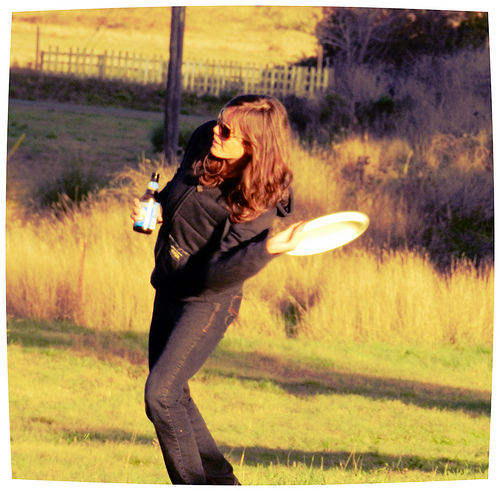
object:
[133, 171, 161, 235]
bottle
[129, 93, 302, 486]
woman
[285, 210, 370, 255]
frisbee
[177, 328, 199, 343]
dark wash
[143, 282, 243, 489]
jeans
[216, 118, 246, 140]
sunglasses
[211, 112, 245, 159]
face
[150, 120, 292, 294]
jacket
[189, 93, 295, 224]
hair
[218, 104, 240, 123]
bangs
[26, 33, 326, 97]
fence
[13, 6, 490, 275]
background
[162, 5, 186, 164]
pole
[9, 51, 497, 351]
tall grass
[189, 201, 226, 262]
black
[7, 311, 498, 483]
grass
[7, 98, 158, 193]
patch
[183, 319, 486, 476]
patch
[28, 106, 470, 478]
field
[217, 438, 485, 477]
shadow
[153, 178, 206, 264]
zipped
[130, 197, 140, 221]
fingers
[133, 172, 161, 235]
beer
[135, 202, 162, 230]
label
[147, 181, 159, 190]
label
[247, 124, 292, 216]
long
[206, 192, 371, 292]
thrown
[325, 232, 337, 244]
white